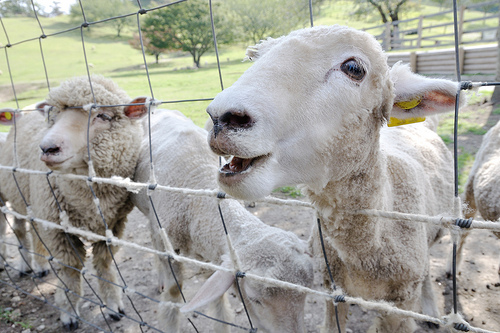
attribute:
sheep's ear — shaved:
[389, 64, 467, 122]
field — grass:
[0, 15, 493, 196]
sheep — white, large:
[207, 27, 464, 331]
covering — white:
[246, 271, 326, 299]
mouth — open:
[211, 146, 270, 180]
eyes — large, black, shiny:
[339, 54, 369, 83]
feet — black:
[64, 315, 80, 329]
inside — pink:
[387, 90, 456, 110]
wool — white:
[273, 81, 358, 160]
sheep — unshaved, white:
[0, 79, 153, 328]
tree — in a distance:
[102, 2, 133, 32]